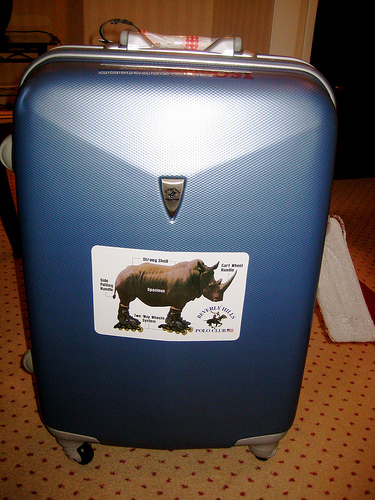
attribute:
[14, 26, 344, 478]
suitcase —   blue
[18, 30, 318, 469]
suitcase — grey, blue, large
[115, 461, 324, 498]
floor — tan, red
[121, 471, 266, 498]
spots — red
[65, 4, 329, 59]
wall — wood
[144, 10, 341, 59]
wood — light brown, brown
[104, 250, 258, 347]
sticker — rhino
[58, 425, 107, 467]
wheel — black, gray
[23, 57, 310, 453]
suitcase — blue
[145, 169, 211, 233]
thing — triangle, silver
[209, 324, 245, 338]
flag — american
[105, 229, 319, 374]
label — white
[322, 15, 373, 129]
door — black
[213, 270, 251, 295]
horn — large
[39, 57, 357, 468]
luggage — blue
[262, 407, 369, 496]
carpet — tan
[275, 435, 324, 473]
dots — red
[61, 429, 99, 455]
wheels — black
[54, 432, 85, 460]
casing — gray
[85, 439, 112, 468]
wheel — back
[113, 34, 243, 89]
handle — retractable, gray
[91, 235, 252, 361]
sticker — saying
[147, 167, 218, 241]
emblem — triangle, stainless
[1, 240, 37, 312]
shadow — behind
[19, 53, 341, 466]
luggage — blue